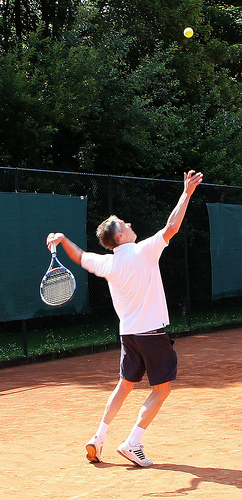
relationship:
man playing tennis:
[44, 167, 203, 465] [183, 26, 198, 40]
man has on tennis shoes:
[44, 167, 203, 465] [118, 442, 154, 468]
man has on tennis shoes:
[44, 167, 203, 465] [87, 435, 103, 464]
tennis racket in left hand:
[40, 240, 76, 307] [46, 231, 64, 246]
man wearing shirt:
[44, 167, 203, 465] [79, 232, 171, 335]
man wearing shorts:
[44, 167, 203, 465] [118, 326, 179, 384]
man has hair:
[44, 167, 203, 465] [95, 214, 120, 250]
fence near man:
[1, 164, 240, 367] [44, 167, 203, 465]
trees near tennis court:
[0, 0, 241, 203] [0, 323, 241, 500]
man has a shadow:
[44, 167, 203, 465] [92, 460, 241, 499]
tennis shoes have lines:
[118, 442, 154, 468] [133, 448, 146, 462]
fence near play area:
[1, 164, 240, 367] [0, 323, 241, 500]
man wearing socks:
[44, 167, 203, 465] [127, 425, 146, 448]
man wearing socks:
[44, 167, 203, 465] [96, 422, 110, 439]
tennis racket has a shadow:
[40, 240, 76, 307] [92, 460, 242, 499]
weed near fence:
[179, 298, 191, 334] [1, 164, 240, 367]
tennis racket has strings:
[40, 240, 76, 307] [42, 270, 71, 304]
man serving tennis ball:
[44, 167, 203, 465] [184, 25, 196, 39]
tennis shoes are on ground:
[118, 442, 154, 468] [0, 323, 241, 500]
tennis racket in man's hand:
[40, 240, 76, 307] [46, 231, 64, 246]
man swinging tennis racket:
[44, 167, 203, 465] [40, 240, 76, 307]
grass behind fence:
[0, 303, 240, 369] [1, 164, 240, 367]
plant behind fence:
[45, 328, 55, 356] [1, 164, 240, 367]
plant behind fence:
[179, 298, 191, 334] [1, 164, 240, 367]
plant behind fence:
[0, 341, 21, 362] [1, 164, 240, 367]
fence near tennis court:
[1, 164, 240, 367] [0, 323, 241, 500]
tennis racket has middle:
[40, 240, 76, 307] [51, 260, 61, 272]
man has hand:
[44, 167, 203, 465] [46, 231, 64, 246]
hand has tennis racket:
[46, 231, 64, 246] [40, 240, 76, 307]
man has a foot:
[44, 167, 203, 465] [118, 442, 154, 468]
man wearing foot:
[44, 167, 203, 465] [118, 442, 154, 468]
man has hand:
[44, 167, 203, 465] [182, 165, 205, 195]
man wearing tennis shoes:
[44, 167, 203, 465] [118, 442, 154, 468]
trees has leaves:
[0, 0, 241, 203] [0, 2, 231, 194]